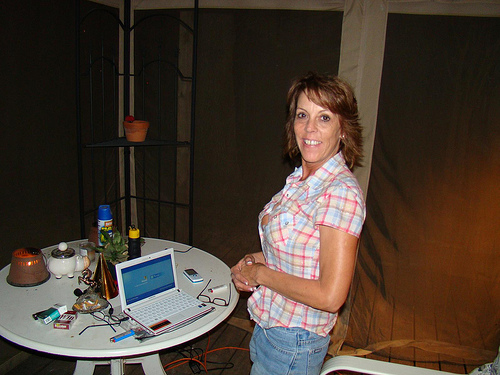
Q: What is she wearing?
A: Plaid top.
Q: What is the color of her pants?
A: Blue.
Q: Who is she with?
A: No one.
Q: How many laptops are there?
A: 1.